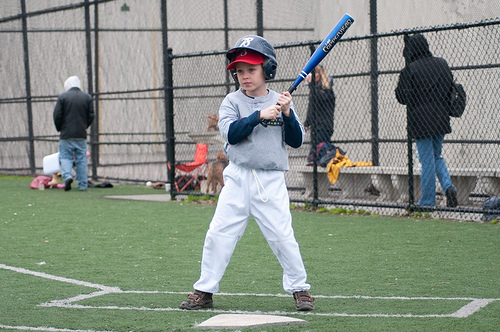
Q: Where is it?
A: This is at the field.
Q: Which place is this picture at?
A: It is at the field.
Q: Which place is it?
A: It is a field.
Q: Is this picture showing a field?
A: Yes, it is showing a field.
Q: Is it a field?
A: Yes, it is a field.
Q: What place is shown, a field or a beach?
A: It is a field.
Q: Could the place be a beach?
A: No, it is a field.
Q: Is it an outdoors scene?
A: Yes, it is outdoors.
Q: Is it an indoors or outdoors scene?
A: It is outdoors.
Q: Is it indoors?
A: No, it is outdoors.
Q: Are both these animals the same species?
A: Yes, all the animals are dogs.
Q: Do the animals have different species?
A: No, all the animals are dogs.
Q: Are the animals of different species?
A: No, all the animals are dogs.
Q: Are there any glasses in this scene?
A: No, there are no glasses.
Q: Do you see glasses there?
A: No, there are no glasses.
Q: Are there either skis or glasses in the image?
A: No, there are no glasses or skis.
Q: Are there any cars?
A: No, there are no cars.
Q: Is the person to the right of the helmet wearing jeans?
A: Yes, the person is wearing jeans.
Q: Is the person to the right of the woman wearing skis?
A: No, the person is wearing jeans.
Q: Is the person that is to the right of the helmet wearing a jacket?
A: Yes, the person is wearing a jacket.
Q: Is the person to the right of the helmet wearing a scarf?
A: No, the person is wearing a jacket.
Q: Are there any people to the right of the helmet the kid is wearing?
A: Yes, there is a person to the right of the helmet.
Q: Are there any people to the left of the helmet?
A: No, the person is to the right of the helmet.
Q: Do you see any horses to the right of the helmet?
A: No, there is a person to the right of the helmet.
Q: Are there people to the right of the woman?
A: Yes, there is a person to the right of the woman.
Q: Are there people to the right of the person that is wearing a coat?
A: Yes, there is a person to the right of the woman.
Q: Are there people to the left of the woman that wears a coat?
A: No, the person is to the right of the woman.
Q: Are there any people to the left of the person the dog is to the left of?
A: No, the person is to the right of the woman.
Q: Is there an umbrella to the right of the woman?
A: No, there is a person to the right of the woman.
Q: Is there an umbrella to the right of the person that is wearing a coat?
A: No, there is a person to the right of the woman.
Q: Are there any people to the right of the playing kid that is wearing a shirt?
A: Yes, there is a person to the right of the child.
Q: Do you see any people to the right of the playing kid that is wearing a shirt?
A: Yes, there is a person to the right of the child.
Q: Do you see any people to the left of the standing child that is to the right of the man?
A: No, the person is to the right of the child.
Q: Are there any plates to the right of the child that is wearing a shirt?
A: No, there is a person to the right of the kid.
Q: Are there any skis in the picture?
A: No, there are no skis.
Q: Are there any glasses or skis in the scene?
A: No, there are no skis or glasses.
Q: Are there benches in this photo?
A: Yes, there is a bench.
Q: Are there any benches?
A: Yes, there is a bench.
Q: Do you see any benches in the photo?
A: Yes, there is a bench.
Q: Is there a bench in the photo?
A: Yes, there is a bench.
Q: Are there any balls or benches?
A: Yes, there is a bench.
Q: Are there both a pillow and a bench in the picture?
A: No, there is a bench but no pillows.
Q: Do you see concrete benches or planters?
A: Yes, there is a concrete bench.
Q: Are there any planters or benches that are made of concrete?
A: Yes, the bench is made of concrete.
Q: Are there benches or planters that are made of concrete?
A: Yes, the bench is made of concrete.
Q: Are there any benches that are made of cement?
A: Yes, there is a bench that is made of cement.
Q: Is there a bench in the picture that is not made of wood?
A: Yes, there is a bench that is made of concrete.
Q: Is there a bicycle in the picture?
A: No, there are no bicycles.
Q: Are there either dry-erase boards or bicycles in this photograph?
A: No, there are no bicycles or dry-erase boards.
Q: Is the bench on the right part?
A: Yes, the bench is on the right of the image.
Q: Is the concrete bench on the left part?
A: No, the bench is on the right of the image.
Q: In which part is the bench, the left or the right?
A: The bench is on the right of the image.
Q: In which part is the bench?
A: The bench is on the right of the image.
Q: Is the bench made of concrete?
A: Yes, the bench is made of concrete.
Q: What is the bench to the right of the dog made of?
A: The bench is made of cement.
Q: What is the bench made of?
A: The bench is made of concrete.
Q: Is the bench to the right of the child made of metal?
A: No, the bench is made of cement.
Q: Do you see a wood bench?
A: No, there is a bench but it is made of concrete.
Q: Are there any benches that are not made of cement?
A: No, there is a bench but it is made of cement.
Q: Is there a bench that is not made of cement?
A: No, there is a bench but it is made of cement.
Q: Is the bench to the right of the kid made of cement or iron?
A: The bench is made of cement.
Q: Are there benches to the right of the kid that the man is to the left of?
A: Yes, there is a bench to the right of the kid.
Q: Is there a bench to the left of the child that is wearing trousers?
A: No, the bench is to the right of the kid.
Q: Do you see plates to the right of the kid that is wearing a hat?
A: No, there is a bench to the right of the kid.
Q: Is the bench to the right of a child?
A: Yes, the bench is to the right of a child.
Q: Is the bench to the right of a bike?
A: No, the bench is to the right of a child.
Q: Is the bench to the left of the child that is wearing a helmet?
A: No, the bench is to the right of the child.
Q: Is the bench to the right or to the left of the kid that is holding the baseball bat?
A: The bench is to the right of the kid.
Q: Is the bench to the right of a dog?
A: Yes, the bench is to the right of a dog.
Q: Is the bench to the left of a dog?
A: No, the bench is to the right of a dog.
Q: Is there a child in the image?
A: Yes, there is a child.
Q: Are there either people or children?
A: Yes, there is a child.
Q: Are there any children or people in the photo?
A: Yes, there is a child.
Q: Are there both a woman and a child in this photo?
A: Yes, there are both a child and a woman.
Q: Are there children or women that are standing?
A: Yes, the child is standing.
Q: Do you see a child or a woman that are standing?
A: Yes, the child is standing.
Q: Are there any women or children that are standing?
A: Yes, the child is standing.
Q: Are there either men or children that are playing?
A: Yes, the child is playing.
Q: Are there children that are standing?
A: Yes, there is a child that is standing.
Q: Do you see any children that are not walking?
A: Yes, there is a child that is standing .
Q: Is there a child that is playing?
A: Yes, there is a child that is playing.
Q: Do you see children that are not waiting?
A: Yes, there is a child that is playing .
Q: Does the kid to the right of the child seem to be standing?
A: Yes, the kid is standing.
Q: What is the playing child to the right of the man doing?
A: The kid is standing.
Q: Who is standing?
A: The child is standing.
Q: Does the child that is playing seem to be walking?
A: No, the kid is standing.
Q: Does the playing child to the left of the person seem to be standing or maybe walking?
A: The child is standing.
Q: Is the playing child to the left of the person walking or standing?
A: The child is standing.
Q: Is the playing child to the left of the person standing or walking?
A: The child is standing.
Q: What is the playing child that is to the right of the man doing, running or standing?
A: The child is standing.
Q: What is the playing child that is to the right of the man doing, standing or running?
A: The child is standing.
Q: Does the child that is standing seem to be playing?
A: Yes, the child is playing.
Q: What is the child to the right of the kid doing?
A: The child is playing.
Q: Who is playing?
A: The kid is playing.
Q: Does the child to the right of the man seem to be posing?
A: No, the kid is playing.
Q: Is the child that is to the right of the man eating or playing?
A: The child is playing.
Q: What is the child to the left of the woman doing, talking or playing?
A: The kid is playing.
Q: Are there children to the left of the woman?
A: Yes, there is a child to the left of the woman.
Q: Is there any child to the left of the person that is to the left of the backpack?
A: Yes, there is a child to the left of the woman.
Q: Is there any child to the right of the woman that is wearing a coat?
A: No, the child is to the left of the woman.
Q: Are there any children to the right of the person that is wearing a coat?
A: No, the child is to the left of the woman.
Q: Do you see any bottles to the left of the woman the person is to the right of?
A: No, there is a child to the left of the woman.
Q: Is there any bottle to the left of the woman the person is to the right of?
A: No, there is a child to the left of the woman.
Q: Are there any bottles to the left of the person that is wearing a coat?
A: No, there is a child to the left of the woman.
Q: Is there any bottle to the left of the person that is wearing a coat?
A: No, there is a child to the left of the woman.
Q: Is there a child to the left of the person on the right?
A: Yes, there is a child to the left of the person.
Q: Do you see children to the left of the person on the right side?
A: Yes, there is a child to the left of the person.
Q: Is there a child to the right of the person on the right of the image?
A: No, the child is to the left of the person.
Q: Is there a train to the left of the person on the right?
A: No, there is a child to the left of the person.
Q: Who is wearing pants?
A: The child is wearing pants.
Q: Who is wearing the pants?
A: The child is wearing pants.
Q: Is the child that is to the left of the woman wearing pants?
A: Yes, the child is wearing pants.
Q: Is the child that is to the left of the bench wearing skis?
A: No, the kid is wearing pants.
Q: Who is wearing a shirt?
A: The kid is wearing a shirt.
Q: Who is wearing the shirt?
A: The kid is wearing a shirt.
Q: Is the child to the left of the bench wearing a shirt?
A: Yes, the child is wearing a shirt.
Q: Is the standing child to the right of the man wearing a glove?
A: No, the kid is wearing a shirt.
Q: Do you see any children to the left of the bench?
A: Yes, there is a child to the left of the bench.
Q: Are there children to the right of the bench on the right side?
A: No, the child is to the left of the bench.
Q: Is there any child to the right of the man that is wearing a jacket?
A: Yes, there is a child to the right of the man.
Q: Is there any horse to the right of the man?
A: No, there is a child to the right of the man.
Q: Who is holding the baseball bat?
A: The kid is holding the baseball bat.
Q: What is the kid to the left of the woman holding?
A: The child is holding the baseball bat.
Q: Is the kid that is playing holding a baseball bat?
A: Yes, the kid is holding a baseball bat.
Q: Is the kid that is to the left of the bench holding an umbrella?
A: No, the kid is holding a baseball bat.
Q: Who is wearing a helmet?
A: The kid is wearing a helmet.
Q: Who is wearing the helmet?
A: The kid is wearing a helmet.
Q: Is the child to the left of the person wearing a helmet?
A: Yes, the child is wearing a helmet.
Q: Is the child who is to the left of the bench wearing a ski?
A: No, the child is wearing a helmet.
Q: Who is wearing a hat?
A: The kid is wearing a hat.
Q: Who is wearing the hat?
A: The kid is wearing a hat.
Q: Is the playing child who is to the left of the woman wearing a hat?
A: Yes, the kid is wearing a hat.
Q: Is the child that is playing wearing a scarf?
A: No, the kid is wearing a hat.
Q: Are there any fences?
A: Yes, there is a fence.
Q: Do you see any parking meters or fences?
A: Yes, there is a fence.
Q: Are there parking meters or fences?
A: Yes, there is a fence.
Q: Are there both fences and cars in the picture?
A: No, there is a fence but no cars.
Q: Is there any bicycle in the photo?
A: No, there are no bicycles.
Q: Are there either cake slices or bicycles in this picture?
A: No, there are no bicycles or cake slices.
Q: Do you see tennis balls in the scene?
A: No, there are no tennis balls.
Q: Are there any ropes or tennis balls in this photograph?
A: No, there are no tennis balls or ropes.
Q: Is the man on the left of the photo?
A: Yes, the man is on the left of the image.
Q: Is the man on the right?
A: No, the man is on the left of the image.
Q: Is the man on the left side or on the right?
A: The man is on the left of the image.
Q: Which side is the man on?
A: The man is on the left of the image.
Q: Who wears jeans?
A: The man wears jeans.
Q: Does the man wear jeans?
A: Yes, the man wears jeans.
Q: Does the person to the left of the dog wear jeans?
A: Yes, the man wears jeans.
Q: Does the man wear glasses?
A: No, the man wears jeans.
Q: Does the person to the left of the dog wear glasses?
A: No, the man wears jeans.